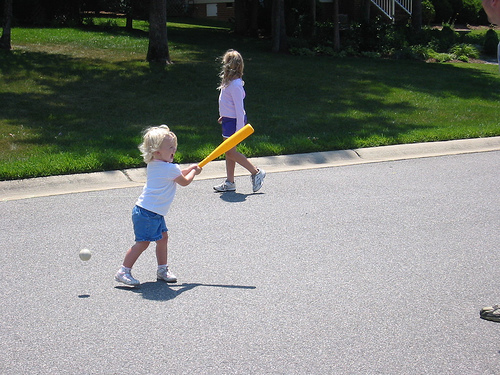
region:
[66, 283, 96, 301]
The shadow of a ball on the pavment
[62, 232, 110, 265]
A white plastic ball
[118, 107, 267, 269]
A little girl swinging a yellow plastic bat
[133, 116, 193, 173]
The sunlight shining on blond hair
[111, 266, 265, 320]
The shadow of a little girl at bat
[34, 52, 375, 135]
The shadows of trees on the grass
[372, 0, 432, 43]
A white stair rail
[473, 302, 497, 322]
The tip of a tennis shoe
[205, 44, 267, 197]
A young girl with wind blowing her hair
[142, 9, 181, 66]
The brown trunk of a tree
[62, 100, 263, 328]
a young girl with a yellow plastic bat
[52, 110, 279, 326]
a young girl misses hitting a baseball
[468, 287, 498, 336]
the foot of the person who threw the ball to the girl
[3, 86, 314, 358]
a girl playing with a bat and baseball on a paved road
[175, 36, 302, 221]
a young girl in the background who is looking away from the camera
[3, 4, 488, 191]
the lawn of a home in the background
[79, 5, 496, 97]
trees in the background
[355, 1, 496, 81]
the front steps of a home in the background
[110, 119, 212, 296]
a toddler girl wearing blue shorts and a pastel colored shirt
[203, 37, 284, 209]
the girl in the background wearing blue shorts and a pink long sleeved top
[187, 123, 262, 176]
Plastic softball bat.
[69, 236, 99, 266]
white ball to hit.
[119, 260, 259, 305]
Shadow of a girl holding a bat.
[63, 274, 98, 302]
Shadow of a ball.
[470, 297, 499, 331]
Someone's foot.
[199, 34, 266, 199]
Older girl walking in the background.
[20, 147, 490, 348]
Kids are playing in the street.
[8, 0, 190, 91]
Tree trunks in the yard in the background.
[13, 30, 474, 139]
Green grass.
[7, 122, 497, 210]
The street's curb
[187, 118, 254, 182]
a yellow plastic bat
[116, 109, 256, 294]
a toddler swinging a yellow bat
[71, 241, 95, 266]
a ball about to hit the ground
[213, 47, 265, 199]
a girl with long hair facing away from the camera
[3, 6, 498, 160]
a lush green front yard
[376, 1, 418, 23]
white handrail on the steps of the house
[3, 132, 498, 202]
white concrete curb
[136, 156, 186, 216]
short sleeved white shirt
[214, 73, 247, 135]
long sleeved light pink shirt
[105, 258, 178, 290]
the toddler's sneakers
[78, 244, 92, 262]
White ball in mid air.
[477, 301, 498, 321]
A shoe on the right side of the picture.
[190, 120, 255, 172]
Yellow plastic baseball bat.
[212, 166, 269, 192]
White tennis shoes on a walking little girl.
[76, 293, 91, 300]
Shadow of a ball on the ground.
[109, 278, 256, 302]
Small girls shadow on the ground in front of her.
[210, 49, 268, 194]
Girl turned away from the camera walking.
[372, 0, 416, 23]
White pair of railings to steps.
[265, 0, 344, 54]
Four tall tree bases on the right.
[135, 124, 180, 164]
The head of a tiny blonde haired girl.